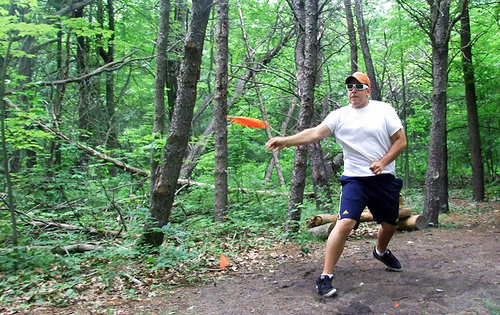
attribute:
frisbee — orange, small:
[229, 109, 263, 130]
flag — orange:
[216, 252, 236, 269]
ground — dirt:
[54, 206, 498, 315]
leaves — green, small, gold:
[242, 243, 268, 268]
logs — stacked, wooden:
[314, 204, 423, 234]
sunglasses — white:
[347, 84, 372, 91]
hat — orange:
[347, 72, 369, 90]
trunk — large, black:
[175, 20, 193, 175]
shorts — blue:
[338, 179, 397, 227]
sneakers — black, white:
[316, 279, 334, 300]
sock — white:
[321, 274, 330, 282]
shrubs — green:
[14, 181, 201, 227]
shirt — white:
[324, 99, 402, 180]